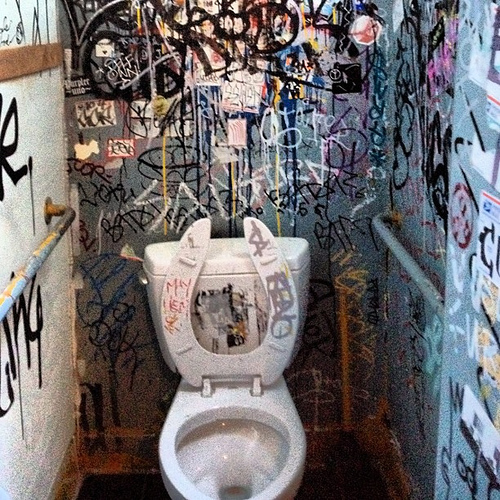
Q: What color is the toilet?
A: White.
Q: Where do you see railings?
A: Both sides of the wall.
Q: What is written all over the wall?
A: Graffiti.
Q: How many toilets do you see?
A: 1.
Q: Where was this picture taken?
A: A bathroom.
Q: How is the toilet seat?
A: Up.